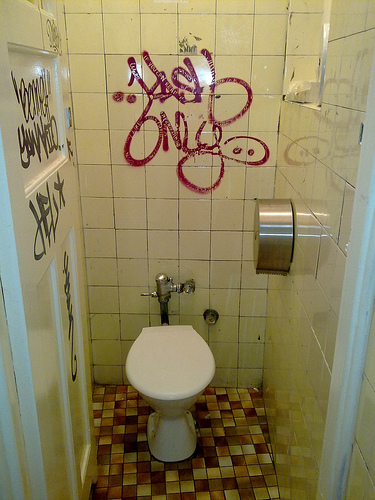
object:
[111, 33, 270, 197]
graffiti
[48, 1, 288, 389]
tiles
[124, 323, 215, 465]
toilet bowl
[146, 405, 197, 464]
tank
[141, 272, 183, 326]
pipe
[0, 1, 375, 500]
photo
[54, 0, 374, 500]
stall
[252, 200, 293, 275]
toilet paper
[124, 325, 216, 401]
lid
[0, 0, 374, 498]
bathroom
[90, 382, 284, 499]
floor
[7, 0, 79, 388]
graffiti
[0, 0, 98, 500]
door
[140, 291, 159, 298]
handle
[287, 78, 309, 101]
grout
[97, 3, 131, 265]
grout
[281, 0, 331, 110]
window